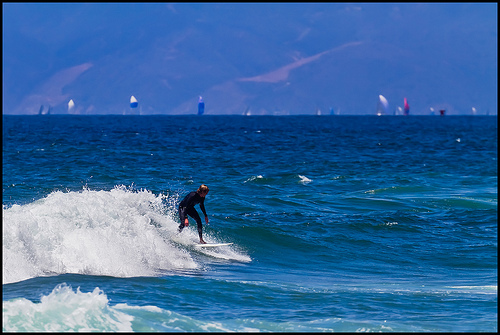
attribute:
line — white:
[195, 272, 499, 299]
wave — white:
[55, 170, 220, 278]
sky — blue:
[31, 15, 474, 84]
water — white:
[38, 149, 316, 275]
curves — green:
[247, 164, 499, 216]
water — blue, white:
[6, 118, 499, 332]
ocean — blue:
[163, 77, 498, 247]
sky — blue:
[184, 10, 389, 104]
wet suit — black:
[172, 188, 209, 243]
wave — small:
[0, 182, 253, 282]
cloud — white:
[10, 57, 94, 111]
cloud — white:
[228, 25, 365, 90]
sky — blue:
[3, 0, 498, 115]